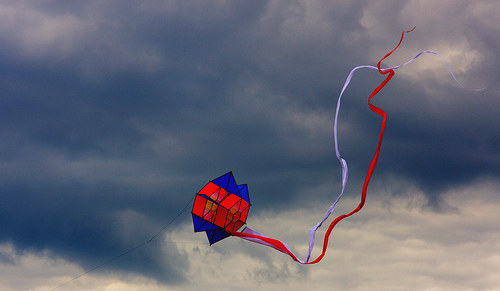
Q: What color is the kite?
A: Red, blue, and black.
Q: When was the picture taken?
A: Daytime.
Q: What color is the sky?
A: Blue.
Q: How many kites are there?
A: One.